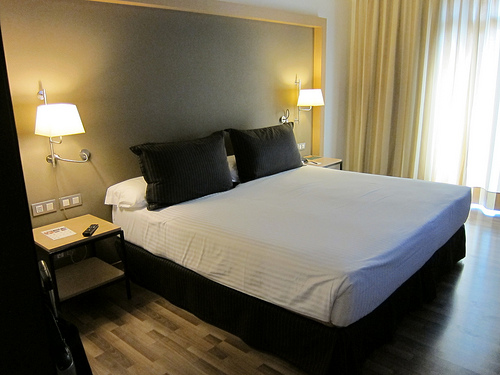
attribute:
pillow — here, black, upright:
[130, 131, 237, 211]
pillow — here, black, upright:
[229, 122, 304, 183]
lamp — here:
[36, 88, 90, 169]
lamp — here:
[298, 90, 324, 112]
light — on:
[36, 104, 85, 136]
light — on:
[297, 89, 326, 106]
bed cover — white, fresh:
[112, 166, 471, 326]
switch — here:
[31, 193, 82, 218]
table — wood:
[33, 214, 132, 316]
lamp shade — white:
[36, 104, 84, 138]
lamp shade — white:
[297, 90, 327, 106]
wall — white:
[1, 1, 350, 230]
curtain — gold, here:
[347, 2, 500, 209]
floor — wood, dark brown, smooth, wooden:
[61, 206, 500, 374]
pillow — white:
[105, 177, 148, 211]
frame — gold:
[108, 1, 328, 28]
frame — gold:
[314, 20, 326, 158]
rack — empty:
[54, 258, 125, 299]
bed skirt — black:
[121, 225, 466, 373]